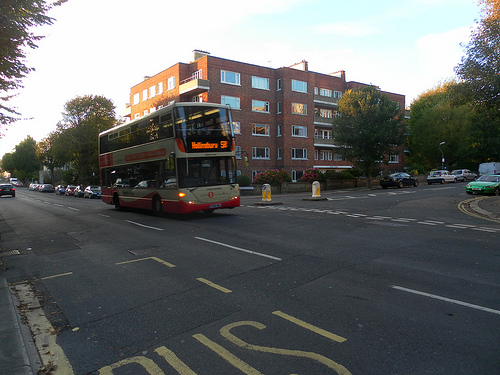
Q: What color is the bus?
A: Gold and red.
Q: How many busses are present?
A: 1.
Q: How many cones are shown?
A: 2.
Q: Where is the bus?
A: On the street.